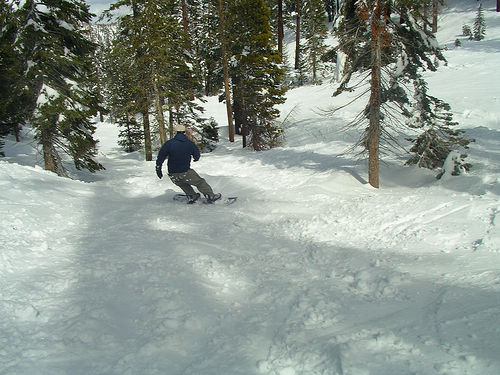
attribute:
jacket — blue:
[156, 136, 198, 172]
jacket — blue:
[163, 145, 202, 173]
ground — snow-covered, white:
[12, 97, 499, 354]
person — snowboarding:
[152, 122, 223, 201]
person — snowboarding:
[150, 120, 239, 207]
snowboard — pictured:
[128, 166, 320, 216]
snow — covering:
[1, 2, 495, 369]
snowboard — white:
[159, 188, 242, 226]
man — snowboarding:
[150, 118, 245, 225]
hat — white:
[170, 122, 190, 132]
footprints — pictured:
[256, 218, 395, 315]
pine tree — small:
[463, 13, 485, 42]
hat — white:
[176, 124, 184, 131]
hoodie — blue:
[154, 127, 204, 172]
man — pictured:
[151, 124, 218, 206]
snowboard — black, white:
[169, 190, 236, 208]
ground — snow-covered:
[6, 12, 485, 362]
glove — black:
[155, 164, 165, 180]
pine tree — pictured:
[215, 2, 292, 149]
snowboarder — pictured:
[158, 120, 224, 206]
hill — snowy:
[1, 6, 494, 371]